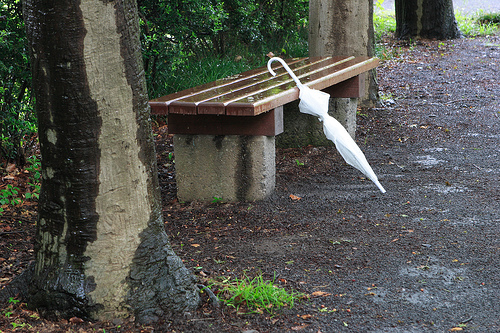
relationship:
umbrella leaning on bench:
[260, 55, 389, 196] [170, 57, 327, 202]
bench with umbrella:
[144, 48, 384, 205] [260, 55, 389, 196]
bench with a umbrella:
[144, 48, 384, 205] [260, 55, 389, 196]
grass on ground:
[207, 272, 294, 314] [393, 155, 498, 326]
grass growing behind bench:
[180, 45, 236, 92] [169, 59, 379, 145]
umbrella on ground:
[274, 62, 382, 202] [216, 48, 488, 320]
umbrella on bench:
[260, 55, 389, 196] [134, 18, 379, 210]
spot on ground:
[368, 255, 490, 313] [0, 16, 499, 330]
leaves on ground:
[367, 50, 452, 116] [0, 16, 499, 330]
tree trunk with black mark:
[10, 4, 199, 321] [119, 7, 197, 314]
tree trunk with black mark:
[10, 4, 199, 321] [30, 7, 83, 309]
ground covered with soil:
[168, 28, 496, 330] [354, 53, 499, 328]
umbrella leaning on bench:
[260, 55, 389, 196] [144, 48, 384, 205]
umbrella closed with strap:
[260, 55, 389, 196] [316, 109, 331, 122]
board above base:
[147, 51, 304, 106] [167, 112, 276, 205]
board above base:
[144, 53, 381, 118] [167, 112, 276, 205]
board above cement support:
[144, 53, 381, 118] [287, 91, 359, 148]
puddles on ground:
[390, 139, 480, 318] [192, 42, 497, 302]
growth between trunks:
[207, 195, 221, 201] [27, 1, 381, 273]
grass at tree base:
[207, 272, 294, 314] [12, 248, 237, 332]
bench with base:
[163, 50, 370, 202] [160, 130, 280, 205]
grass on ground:
[213, 263, 297, 313] [0, 16, 499, 330]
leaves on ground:
[289, 311, 311, 331] [0, 16, 499, 330]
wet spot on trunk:
[0, 3, 100, 318] [5, 1, 201, 323]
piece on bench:
[165, 104, 285, 137] [144, 48, 384, 205]